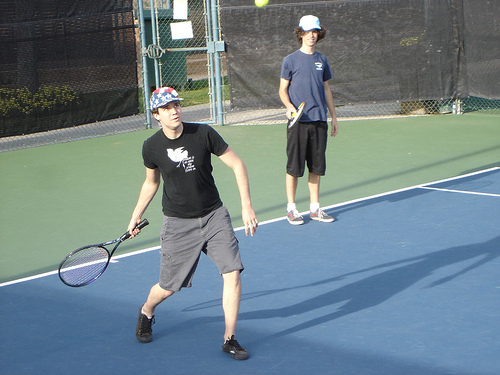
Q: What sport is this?
A: Tennis.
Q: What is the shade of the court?
A: Green and blue.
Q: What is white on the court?
A: Lines.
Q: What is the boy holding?
A: A racket.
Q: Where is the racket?
A: In the boy's hand.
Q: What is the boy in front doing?
A: Swinging.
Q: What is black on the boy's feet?
A: Shoes.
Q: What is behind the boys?
A: A fence.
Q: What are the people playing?
A: Tennis.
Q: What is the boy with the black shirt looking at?
A: The ball.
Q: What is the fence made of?
A: Metal.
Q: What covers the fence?
A: A black mesh cover.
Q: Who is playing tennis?
A: Two boys.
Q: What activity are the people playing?
A: Tennis.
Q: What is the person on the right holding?
A: Tennis racket.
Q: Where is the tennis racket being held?
A: Right hand.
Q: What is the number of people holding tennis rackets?
A: Two.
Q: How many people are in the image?
A: Two.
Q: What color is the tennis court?
A: Blue.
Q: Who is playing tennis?
A: The people.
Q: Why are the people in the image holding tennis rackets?
A: Playing tennis.